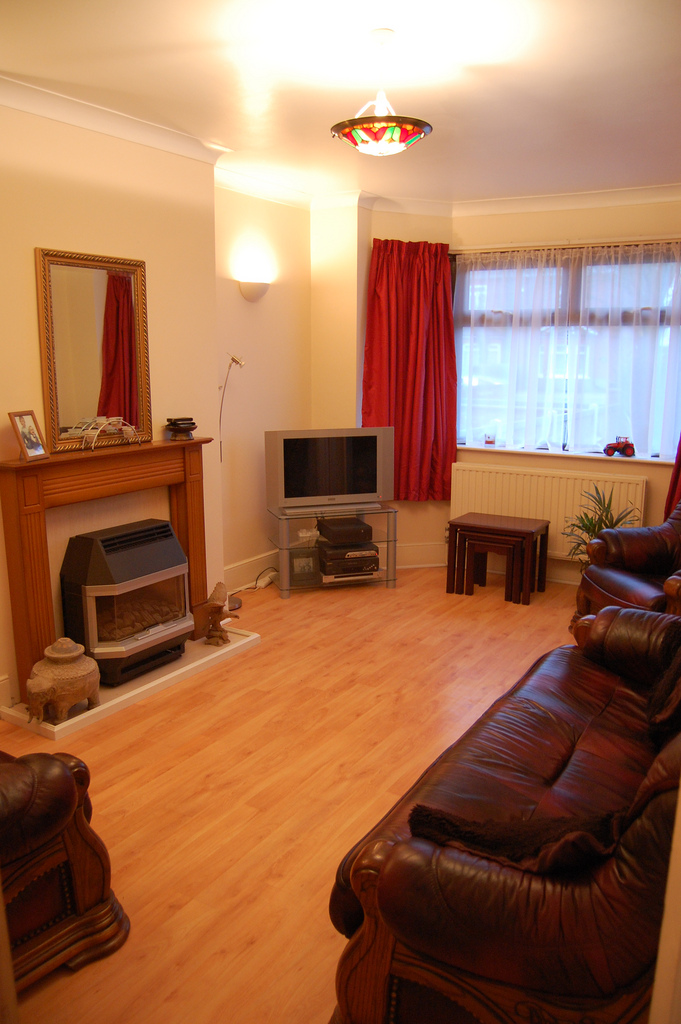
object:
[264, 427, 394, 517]
tv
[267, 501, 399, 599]
stand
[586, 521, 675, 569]
cushion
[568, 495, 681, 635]
couch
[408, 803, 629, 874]
cushion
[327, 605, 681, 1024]
couch